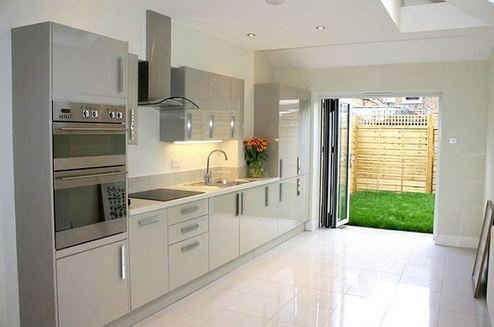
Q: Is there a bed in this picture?
A: No, there are no beds.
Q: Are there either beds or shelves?
A: No, there are no beds or shelves.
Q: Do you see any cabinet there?
A: Yes, there is a cabinet.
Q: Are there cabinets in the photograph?
A: Yes, there is a cabinet.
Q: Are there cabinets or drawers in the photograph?
A: Yes, there is a cabinet.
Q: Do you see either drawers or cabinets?
A: Yes, there is a cabinet.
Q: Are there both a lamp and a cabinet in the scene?
A: No, there is a cabinet but no lamps.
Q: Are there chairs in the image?
A: No, there are no chairs.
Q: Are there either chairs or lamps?
A: No, there are no chairs or lamps.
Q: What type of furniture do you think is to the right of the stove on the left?
A: The piece of furniture is a cabinet.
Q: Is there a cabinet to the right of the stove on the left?
A: Yes, there is a cabinet to the right of the stove.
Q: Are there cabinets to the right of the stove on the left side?
A: Yes, there is a cabinet to the right of the stove.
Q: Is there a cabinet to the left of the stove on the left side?
A: No, the cabinet is to the right of the stove.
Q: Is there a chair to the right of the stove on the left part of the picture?
A: No, there is a cabinet to the right of the stove.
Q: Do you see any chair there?
A: No, there are no chairs.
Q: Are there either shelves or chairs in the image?
A: No, there are no chairs or shelves.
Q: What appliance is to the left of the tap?
A: The appliance is a stove.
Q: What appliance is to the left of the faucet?
A: The appliance is a stove.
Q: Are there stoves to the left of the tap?
A: Yes, there is a stove to the left of the tap.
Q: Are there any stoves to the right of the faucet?
A: No, the stove is to the left of the faucet.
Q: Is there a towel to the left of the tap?
A: No, there is a stove to the left of the tap.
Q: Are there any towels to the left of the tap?
A: No, there is a stove to the left of the tap.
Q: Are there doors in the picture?
A: Yes, there is a door.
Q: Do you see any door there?
A: Yes, there is a door.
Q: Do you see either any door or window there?
A: Yes, there is a door.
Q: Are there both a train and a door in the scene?
A: No, there is a door but no trains.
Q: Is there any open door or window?
A: Yes, there is an open door.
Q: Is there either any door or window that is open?
A: Yes, the door is open.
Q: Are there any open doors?
A: Yes, there is an open door.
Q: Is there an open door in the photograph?
A: Yes, there is an open door.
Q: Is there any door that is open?
A: Yes, there is a door that is open.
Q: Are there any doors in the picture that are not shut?
A: Yes, there is a open door.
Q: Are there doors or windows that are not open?
A: No, there is a door but it is open.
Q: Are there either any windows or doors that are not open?
A: No, there is a door but it is open.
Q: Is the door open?
A: Yes, the door is open.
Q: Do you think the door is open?
A: Yes, the door is open.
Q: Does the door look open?
A: Yes, the door is open.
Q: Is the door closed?
A: No, the door is open.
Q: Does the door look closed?
A: No, the door is open.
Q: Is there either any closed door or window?
A: No, there is a door but it is open.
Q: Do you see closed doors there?
A: No, there is a door but it is open.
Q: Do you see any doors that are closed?
A: No, there is a door but it is open.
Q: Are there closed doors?
A: No, there is a door but it is open.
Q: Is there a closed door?
A: No, there is a door but it is open.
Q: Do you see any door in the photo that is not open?
A: No, there is a door but it is open.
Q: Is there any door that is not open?
A: No, there is a door but it is open.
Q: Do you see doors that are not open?
A: No, there is a door but it is open.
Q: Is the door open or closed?
A: The door is open.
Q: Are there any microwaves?
A: No, there are no microwaves.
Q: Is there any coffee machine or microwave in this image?
A: No, there are no microwaves or coffee makers.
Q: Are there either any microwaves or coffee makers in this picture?
A: No, there are no microwaves or coffee makers.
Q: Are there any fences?
A: Yes, there is a fence.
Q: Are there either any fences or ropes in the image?
A: Yes, there is a fence.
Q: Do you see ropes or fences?
A: Yes, there is a fence.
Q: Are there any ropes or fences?
A: Yes, there is a fence.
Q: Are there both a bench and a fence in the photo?
A: No, there is a fence but no benches.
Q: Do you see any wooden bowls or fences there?
A: Yes, there is a wood fence.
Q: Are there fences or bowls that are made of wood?
A: Yes, the fence is made of wood.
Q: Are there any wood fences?
A: Yes, there is a fence that is made of wood.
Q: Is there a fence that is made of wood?
A: Yes, there is a fence that is made of wood.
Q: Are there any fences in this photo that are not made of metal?
A: Yes, there is a fence that is made of wood.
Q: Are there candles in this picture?
A: No, there are no candles.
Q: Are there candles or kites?
A: No, there are no candles or kites.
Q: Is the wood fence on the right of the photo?
A: Yes, the fence is on the right of the image.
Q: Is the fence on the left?
A: No, the fence is on the right of the image.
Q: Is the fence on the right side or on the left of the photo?
A: The fence is on the right of the image.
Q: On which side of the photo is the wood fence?
A: The fence is on the right of the image.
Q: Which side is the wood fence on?
A: The fence is on the right of the image.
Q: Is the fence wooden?
A: Yes, the fence is wooden.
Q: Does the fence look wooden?
A: Yes, the fence is wooden.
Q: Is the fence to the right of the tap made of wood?
A: Yes, the fence is made of wood.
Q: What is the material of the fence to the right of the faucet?
A: The fence is made of wood.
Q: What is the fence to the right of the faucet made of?
A: The fence is made of wood.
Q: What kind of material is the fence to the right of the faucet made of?
A: The fence is made of wood.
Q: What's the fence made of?
A: The fence is made of wood.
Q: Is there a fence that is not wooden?
A: No, there is a fence but it is wooden.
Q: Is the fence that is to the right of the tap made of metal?
A: No, the fence is made of wood.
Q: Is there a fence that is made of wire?
A: No, there is a fence but it is made of wood.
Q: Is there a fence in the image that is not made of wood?
A: No, there is a fence but it is made of wood.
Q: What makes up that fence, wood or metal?
A: The fence is made of wood.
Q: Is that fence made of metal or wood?
A: The fence is made of wood.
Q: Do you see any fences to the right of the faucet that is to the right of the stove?
A: Yes, there is a fence to the right of the faucet.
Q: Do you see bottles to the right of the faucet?
A: No, there is a fence to the right of the faucet.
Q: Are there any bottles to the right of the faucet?
A: No, there is a fence to the right of the faucet.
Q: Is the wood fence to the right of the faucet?
A: Yes, the fence is to the right of the faucet.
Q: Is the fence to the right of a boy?
A: No, the fence is to the right of the faucet.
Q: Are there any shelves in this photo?
A: No, there are no shelves.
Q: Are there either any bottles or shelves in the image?
A: No, there are no shelves or bottles.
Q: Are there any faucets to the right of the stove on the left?
A: Yes, there is a faucet to the right of the stove.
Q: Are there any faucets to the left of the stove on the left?
A: No, the faucet is to the right of the stove.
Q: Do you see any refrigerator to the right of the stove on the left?
A: No, there is a faucet to the right of the stove.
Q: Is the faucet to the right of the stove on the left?
A: Yes, the faucet is to the right of the stove.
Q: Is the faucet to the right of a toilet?
A: No, the faucet is to the right of the stove.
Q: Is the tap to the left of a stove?
A: No, the tap is to the right of a stove.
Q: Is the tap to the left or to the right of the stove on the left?
A: The tap is to the right of the stove.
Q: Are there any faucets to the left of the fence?
A: Yes, there is a faucet to the left of the fence.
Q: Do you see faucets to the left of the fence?
A: Yes, there is a faucet to the left of the fence.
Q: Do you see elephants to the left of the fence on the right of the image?
A: No, there is a faucet to the left of the fence.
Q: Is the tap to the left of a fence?
A: Yes, the tap is to the left of a fence.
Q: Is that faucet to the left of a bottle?
A: No, the faucet is to the left of a fence.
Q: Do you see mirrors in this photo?
A: Yes, there is a mirror.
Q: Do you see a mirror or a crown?
A: Yes, there is a mirror.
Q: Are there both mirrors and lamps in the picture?
A: No, there is a mirror but no lamps.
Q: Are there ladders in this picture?
A: No, there are no ladders.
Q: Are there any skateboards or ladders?
A: No, there are no ladders or skateboards.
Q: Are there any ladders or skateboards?
A: No, there are no ladders or skateboards.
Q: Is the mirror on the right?
A: Yes, the mirror is on the right of the image.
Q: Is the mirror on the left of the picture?
A: No, the mirror is on the right of the image.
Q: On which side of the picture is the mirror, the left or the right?
A: The mirror is on the right of the image.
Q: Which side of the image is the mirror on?
A: The mirror is on the right of the image.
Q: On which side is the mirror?
A: The mirror is on the right of the image.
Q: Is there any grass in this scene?
A: Yes, there is grass.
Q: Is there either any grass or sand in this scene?
A: Yes, there is grass.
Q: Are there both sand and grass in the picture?
A: No, there is grass but no sand.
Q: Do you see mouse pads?
A: No, there are no mouse pads.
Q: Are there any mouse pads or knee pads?
A: No, there are no mouse pads or knee pads.